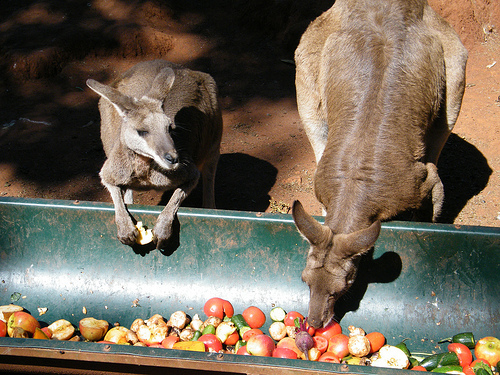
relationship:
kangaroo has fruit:
[85, 58, 222, 253] [133, 221, 156, 247]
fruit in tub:
[8, 312, 39, 340] [2, 196, 500, 374]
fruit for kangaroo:
[133, 221, 156, 247] [85, 58, 222, 253]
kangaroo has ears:
[85, 58, 222, 253] [86, 78, 138, 121]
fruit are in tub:
[8, 312, 39, 340] [2, 196, 500, 374]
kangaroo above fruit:
[85, 58, 222, 253] [8, 312, 39, 340]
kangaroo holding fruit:
[85, 58, 222, 253] [133, 221, 156, 247]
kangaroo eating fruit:
[85, 58, 222, 253] [133, 221, 156, 247]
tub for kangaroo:
[2, 196, 500, 374] [85, 58, 222, 253]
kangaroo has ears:
[287, 1, 469, 330] [291, 196, 333, 253]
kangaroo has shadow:
[85, 58, 222, 253] [159, 153, 280, 213]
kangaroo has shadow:
[287, 1, 469, 330] [384, 127, 492, 224]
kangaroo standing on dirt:
[85, 58, 222, 253] [3, 1, 498, 233]